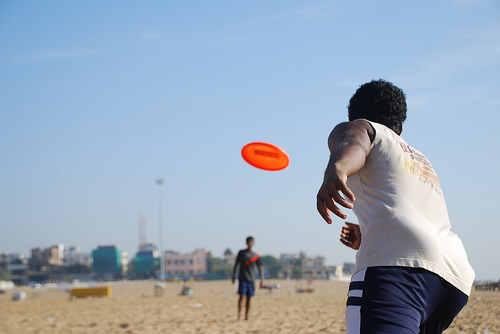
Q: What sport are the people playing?
A: Frisbee.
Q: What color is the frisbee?
A: Orange.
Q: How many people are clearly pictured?
A: Two.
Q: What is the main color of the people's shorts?
A: Blue.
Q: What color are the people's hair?
A: Black.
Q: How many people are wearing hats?
A: None.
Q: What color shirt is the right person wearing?
A: White.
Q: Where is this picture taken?
A: At the beach.